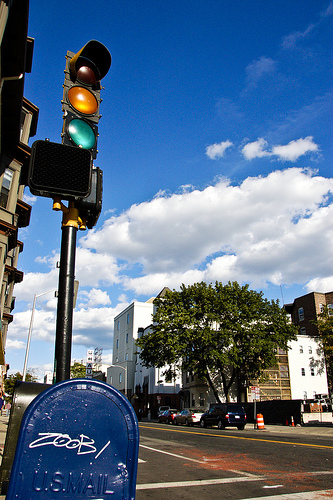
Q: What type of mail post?
A: Blue and US.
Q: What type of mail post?
A: Blue.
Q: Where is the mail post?
A: Below the traffic light.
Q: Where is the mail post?
A: Near a black post.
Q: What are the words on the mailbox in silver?
A: ZOOB.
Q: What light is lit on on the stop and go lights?
A: Green.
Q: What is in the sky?
A: Clouds.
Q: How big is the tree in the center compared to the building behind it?
A: Larger than the building.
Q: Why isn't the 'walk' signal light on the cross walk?
A: It's broken.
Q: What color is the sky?
A: Blue.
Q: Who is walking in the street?
A: No One.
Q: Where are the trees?
A: Beside the building.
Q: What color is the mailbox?
A: Blue.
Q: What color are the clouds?
A: White.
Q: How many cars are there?
A: 3.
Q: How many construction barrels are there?
A: 1.